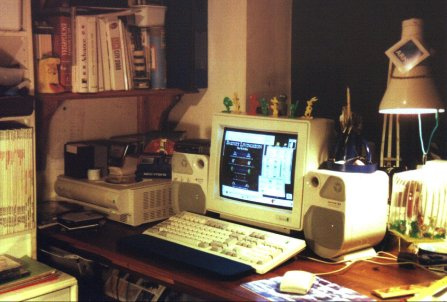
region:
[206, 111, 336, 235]
computer monitor is on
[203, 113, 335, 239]
computer monitor is tan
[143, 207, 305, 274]
keyboard is in front of monitor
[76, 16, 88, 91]
white book on shelf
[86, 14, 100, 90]
white book on shelf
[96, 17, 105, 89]
white book on shelf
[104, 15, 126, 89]
white book on shelf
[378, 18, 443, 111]
white lamp is on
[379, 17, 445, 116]
white lamp over table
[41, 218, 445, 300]
computer table is wooden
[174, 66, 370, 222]
a computer on a desk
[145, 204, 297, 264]
a heyboard on a desk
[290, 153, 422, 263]
a speaker on a desk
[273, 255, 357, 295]
a mouse on a desk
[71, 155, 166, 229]
a fax machine on a desk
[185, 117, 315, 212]
the screen of a computer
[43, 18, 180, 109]
books on a shelf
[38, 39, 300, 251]
books near a computer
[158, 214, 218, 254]
white keys on a key board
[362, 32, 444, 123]
a light on a desk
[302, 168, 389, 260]
A big white speaker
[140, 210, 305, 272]
A white keyboard on a table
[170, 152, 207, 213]
A large white sub speaker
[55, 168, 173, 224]
An electronic machine on a table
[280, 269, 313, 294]
A computer mouse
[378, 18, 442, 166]
A metal light fixture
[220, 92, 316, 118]
Small action figure toys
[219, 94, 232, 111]
A green action figure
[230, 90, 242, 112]
A yellow action figure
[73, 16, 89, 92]
A white book next to other books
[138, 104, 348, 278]
large white computer on the desk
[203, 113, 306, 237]
the monitor is on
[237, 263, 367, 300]
mouse on a mouse pad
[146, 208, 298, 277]
white keys on the keyboard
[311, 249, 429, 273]
white cord on the desk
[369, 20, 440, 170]
lamp is on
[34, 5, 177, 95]
books on the shelf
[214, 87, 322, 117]
figurines on top of the computer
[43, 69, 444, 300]
desk is cluttered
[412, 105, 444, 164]
wires hanging down from the lamp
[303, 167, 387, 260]
cpu next to computer monitor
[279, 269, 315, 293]
computer mouse in front of cpu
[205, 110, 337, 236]
computer monitor behind keyboard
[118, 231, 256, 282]
wrist cushion in front of keyboard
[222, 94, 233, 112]
green figurine on top of computer monitor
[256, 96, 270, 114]
green figurine on top of computer monitor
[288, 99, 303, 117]
green figurine on top of computer monitor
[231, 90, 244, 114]
yellow figurine on top of computer monitor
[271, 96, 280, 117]
yellow figurine on top of computer monitor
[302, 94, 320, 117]
yellow figurine on top of computer monitor